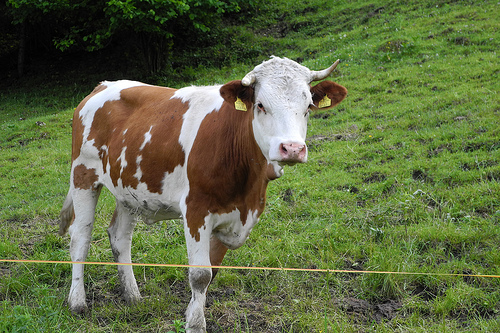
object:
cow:
[57, 54, 349, 332]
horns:
[311, 59, 340, 81]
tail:
[58, 174, 76, 237]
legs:
[65, 155, 100, 316]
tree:
[2, 1, 88, 88]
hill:
[0, 0, 500, 333]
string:
[0, 259, 499, 278]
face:
[251, 82, 314, 164]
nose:
[279, 142, 306, 162]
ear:
[219, 78, 257, 105]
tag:
[235, 97, 247, 111]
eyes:
[256, 102, 267, 111]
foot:
[67, 303, 91, 319]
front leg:
[183, 205, 212, 332]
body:
[70, 79, 284, 250]